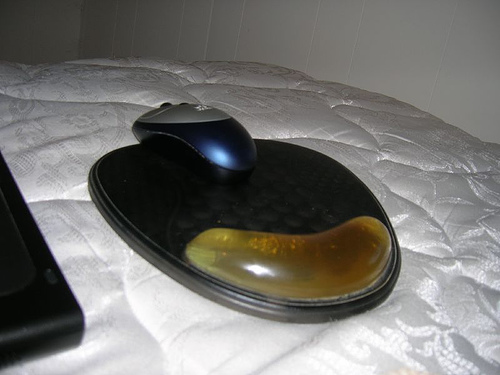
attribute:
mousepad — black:
[86, 138, 402, 326]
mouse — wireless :
[71, 72, 444, 335]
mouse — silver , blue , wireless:
[133, 100, 255, 185]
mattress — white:
[343, 122, 449, 155]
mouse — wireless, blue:
[124, 82, 276, 195]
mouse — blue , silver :
[121, 69, 258, 183]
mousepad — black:
[150, 160, 370, 291]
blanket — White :
[6, 50, 496, 367]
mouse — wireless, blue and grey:
[125, 96, 264, 179]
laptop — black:
[0, 149, 84, 373]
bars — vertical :
[156, 4, 246, 55]